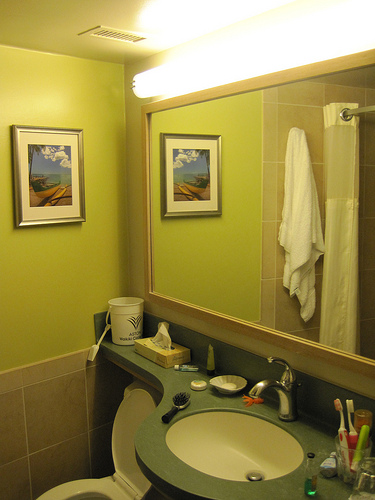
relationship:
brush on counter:
[161, 388, 188, 424] [96, 337, 373, 499]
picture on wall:
[11, 123, 86, 228] [2, 58, 130, 374]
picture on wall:
[158, 131, 222, 218] [149, 80, 374, 361]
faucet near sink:
[242, 355, 298, 423] [160, 399, 307, 484]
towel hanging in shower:
[280, 124, 328, 328] [267, 78, 373, 370]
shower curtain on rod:
[317, 99, 358, 357] [343, 102, 374, 117]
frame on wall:
[9, 121, 86, 227] [2, 58, 130, 374]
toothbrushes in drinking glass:
[333, 399, 366, 453] [332, 437, 372, 498]